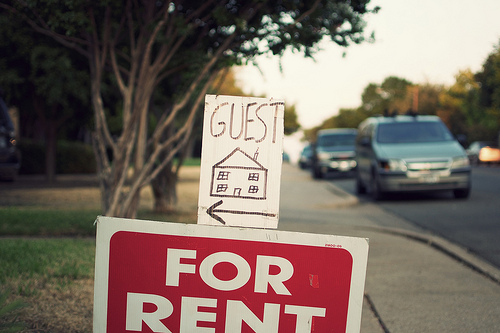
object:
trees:
[446, 42, 500, 154]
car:
[353, 113, 472, 198]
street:
[274, 116, 498, 330]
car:
[311, 127, 357, 176]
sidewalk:
[262, 143, 500, 333]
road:
[307, 123, 499, 270]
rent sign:
[96, 212, 373, 333]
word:
[209, 100, 285, 144]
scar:
[308, 273, 320, 288]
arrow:
[204, 200, 275, 225]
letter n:
[226, 300, 278, 333]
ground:
[0, 160, 497, 329]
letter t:
[283, 304, 327, 333]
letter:
[198, 251, 252, 292]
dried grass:
[13, 282, 93, 333]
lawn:
[0, 185, 92, 332]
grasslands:
[0, 189, 98, 330]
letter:
[174, 293, 218, 333]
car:
[455, 137, 482, 165]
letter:
[122, 287, 172, 333]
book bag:
[92, 212, 365, 333]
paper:
[188, 93, 286, 230]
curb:
[277, 159, 500, 333]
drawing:
[200, 95, 281, 228]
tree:
[0, 0, 376, 229]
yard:
[0, 158, 195, 329]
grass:
[1, 205, 176, 291]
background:
[10, 20, 500, 221]